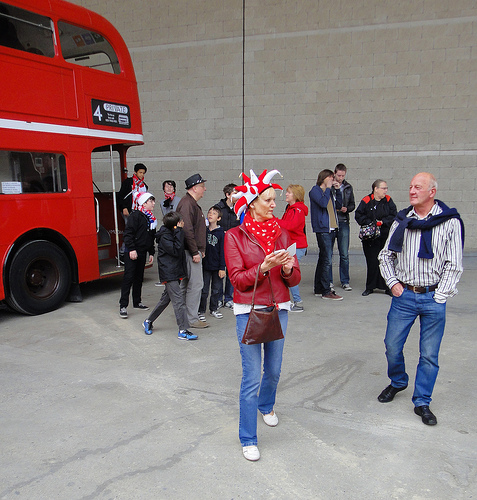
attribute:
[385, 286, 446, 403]
jeans — blue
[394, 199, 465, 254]
sweater — tied, blue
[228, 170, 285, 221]
hat — white, red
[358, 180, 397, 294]
person — waiting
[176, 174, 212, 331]
grandpa — waiting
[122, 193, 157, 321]
person — waiting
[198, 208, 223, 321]
kid — looking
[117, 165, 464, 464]
crowd — standing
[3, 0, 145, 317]
bus — red, double decker, large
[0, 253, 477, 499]
floor — concrete, concret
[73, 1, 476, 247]
wall — grey, stone, drab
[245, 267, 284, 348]
purse — brown, hanging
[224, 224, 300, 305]
jacket — leather, red, dark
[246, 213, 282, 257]
scarf — red, white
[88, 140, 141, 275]
door — open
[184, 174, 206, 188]
hat — black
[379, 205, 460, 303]
shirt — striped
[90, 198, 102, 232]
railing — metal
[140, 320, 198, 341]
sneakers — blue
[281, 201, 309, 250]
sweatshirt — red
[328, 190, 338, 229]
scarf — brown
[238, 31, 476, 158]
tiles — gray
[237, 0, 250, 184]
lines — deep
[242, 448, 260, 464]
sneaker — white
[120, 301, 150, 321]
sneakers — black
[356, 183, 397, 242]
jacket — black, red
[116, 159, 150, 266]
passenger — stepping